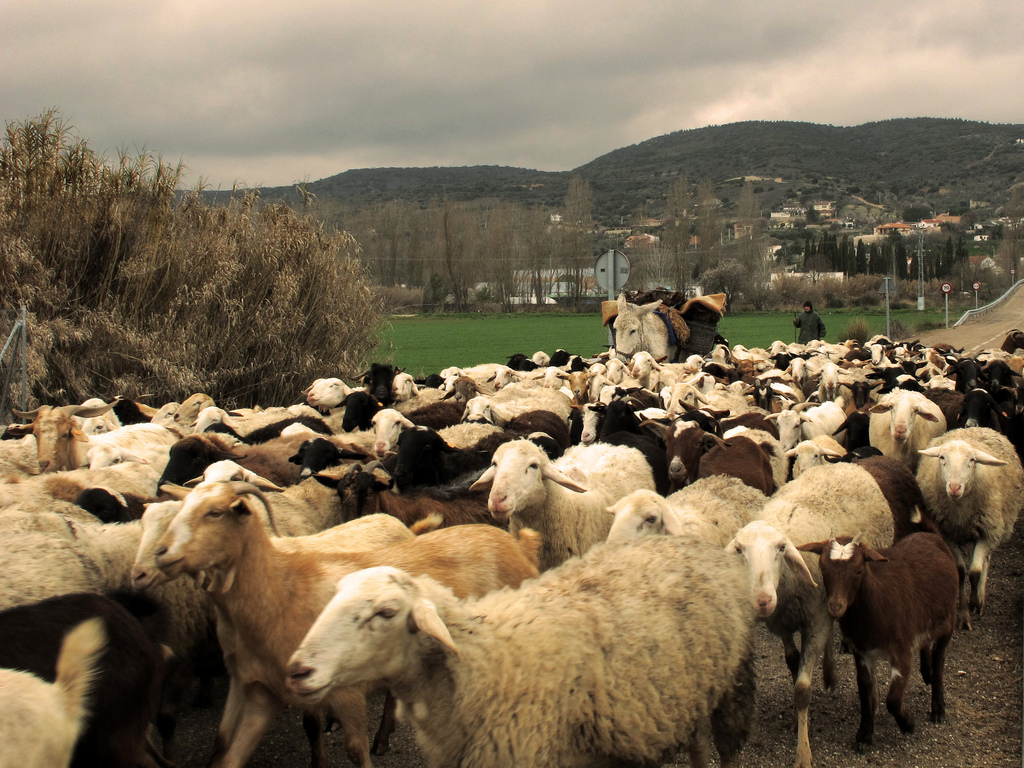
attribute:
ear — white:
[397, 610, 523, 712]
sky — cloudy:
[194, 37, 838, 184]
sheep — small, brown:
[771, 504, 1007, 755]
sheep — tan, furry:
[272, 553, 787, 765]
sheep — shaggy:
[258, 513, 770, 764]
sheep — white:
[308, 499, 784, 763]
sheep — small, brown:
[770, 475, 1015, 765]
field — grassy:
[356, 296, 627, 396]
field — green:
[341, 267, 601, 412]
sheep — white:
[293, 535, 765, 765]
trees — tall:
[3, 170, 420, 438]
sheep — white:
[265, 553, 857, 750]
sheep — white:
[883, 402, 1022, 610]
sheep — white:
[583, 446, 798, 585]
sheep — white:
[693, 443, 923, 742]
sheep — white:
[469, 374, 580, 431]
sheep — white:
[356, 398, 542, 491]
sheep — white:
[283, 353, 385, 429]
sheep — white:
[801, 346, 922, 448]